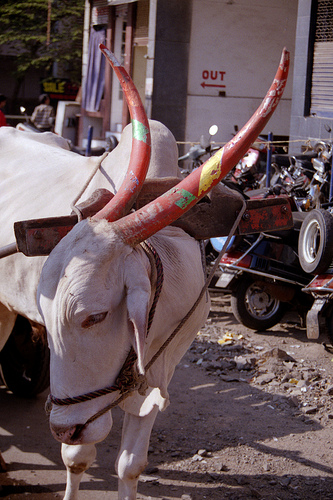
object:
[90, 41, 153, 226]
horns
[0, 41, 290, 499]
goat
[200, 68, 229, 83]
out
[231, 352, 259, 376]
garbage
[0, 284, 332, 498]
street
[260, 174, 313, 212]
junk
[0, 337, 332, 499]
shadow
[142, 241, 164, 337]
rope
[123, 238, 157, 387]
neck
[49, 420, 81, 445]
nose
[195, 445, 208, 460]
rocks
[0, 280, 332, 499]
ground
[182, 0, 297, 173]
wall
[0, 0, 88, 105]
tree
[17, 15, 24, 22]
leaves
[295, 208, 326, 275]
tire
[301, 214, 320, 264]
rim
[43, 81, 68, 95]
sign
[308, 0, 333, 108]
curtain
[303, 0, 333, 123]
window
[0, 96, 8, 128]
person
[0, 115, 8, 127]
shirt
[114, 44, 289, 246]
horn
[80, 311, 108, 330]
eye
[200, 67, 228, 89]
sign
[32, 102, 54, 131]
shirt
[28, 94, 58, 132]
man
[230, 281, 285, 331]
tire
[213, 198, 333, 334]
motorcycle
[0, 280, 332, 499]
dirt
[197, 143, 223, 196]
paint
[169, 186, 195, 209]
paint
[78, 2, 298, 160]
building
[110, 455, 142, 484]
knee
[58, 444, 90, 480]
knee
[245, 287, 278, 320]
rim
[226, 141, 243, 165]
red